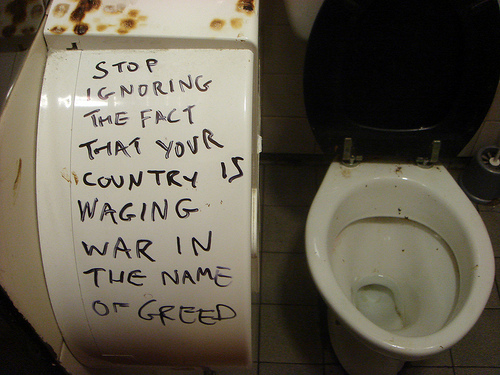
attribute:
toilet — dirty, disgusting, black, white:
[302, 4, 496, 373]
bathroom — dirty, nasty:
[1, 0, 498, 371]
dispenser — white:
[40, 3, 253, 368]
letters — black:
[80, 57, 243, 328]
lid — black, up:
[302, 2, 498, 169]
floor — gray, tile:
[260, 160, 497, 372]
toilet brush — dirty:
[455, 145, 496, 207]